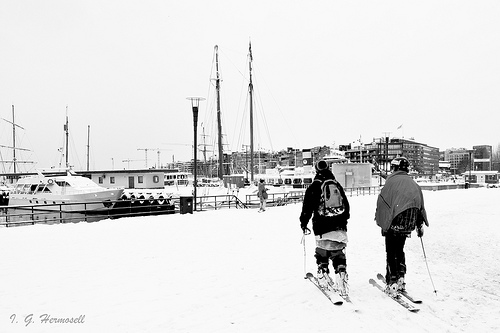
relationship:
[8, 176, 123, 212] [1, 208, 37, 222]
boat on water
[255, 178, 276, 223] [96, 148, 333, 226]
woman walking on pier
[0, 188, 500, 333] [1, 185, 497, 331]
snow on top of ground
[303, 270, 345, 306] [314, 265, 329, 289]
ski on foot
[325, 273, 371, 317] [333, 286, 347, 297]
ski on foot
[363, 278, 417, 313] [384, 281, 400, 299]
ski on foot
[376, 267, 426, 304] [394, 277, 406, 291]
ski on foot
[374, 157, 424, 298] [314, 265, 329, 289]
people has foot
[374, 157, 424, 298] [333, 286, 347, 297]
people has foot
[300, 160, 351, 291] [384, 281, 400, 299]
person has foot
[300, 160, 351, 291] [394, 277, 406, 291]
person has foot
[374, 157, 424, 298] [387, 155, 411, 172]
people wearing helmet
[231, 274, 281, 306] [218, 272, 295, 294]
snow on ground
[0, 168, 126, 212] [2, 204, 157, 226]
boat on water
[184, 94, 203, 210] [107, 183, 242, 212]
light pole near pier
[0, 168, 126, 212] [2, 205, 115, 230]
boat in water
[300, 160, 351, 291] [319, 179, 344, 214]
person has backpack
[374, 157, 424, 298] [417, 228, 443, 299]
people holding ski pole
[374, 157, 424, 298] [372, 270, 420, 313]
people on skis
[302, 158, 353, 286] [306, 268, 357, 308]
person on skis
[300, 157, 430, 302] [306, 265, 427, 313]
people on skis